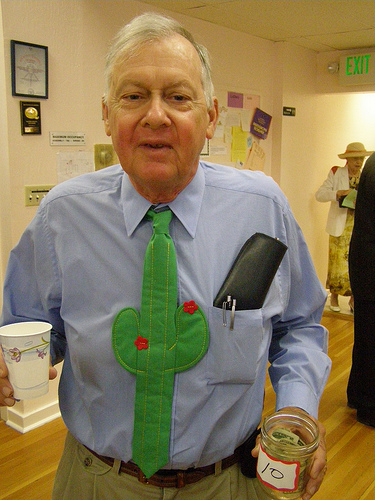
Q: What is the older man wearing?
A: A cactus tie.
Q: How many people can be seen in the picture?
A: 3.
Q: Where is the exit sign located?
A: In background above doorway.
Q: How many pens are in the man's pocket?
A: 2.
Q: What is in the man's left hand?
A: A jar with money in it.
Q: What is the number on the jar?
A: 10.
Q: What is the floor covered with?
A: Hardwood.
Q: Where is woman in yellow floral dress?
A: Coming in through the doorway, under exit sign.